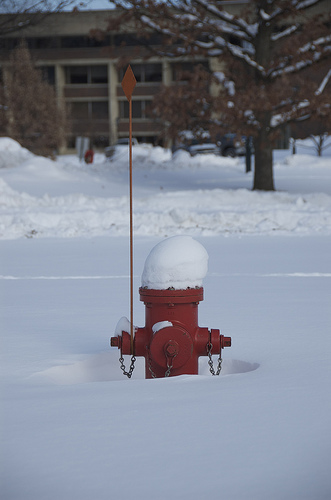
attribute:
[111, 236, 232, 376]
fire hydrant — red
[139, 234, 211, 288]
snow — sunken, white, disheveled, undisturbed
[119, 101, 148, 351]
pole — orange, metal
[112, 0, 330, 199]
tree — large, small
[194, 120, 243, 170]
truck — white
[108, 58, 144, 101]
diamond — orange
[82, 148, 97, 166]
shirt — red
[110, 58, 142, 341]
flag — red, orange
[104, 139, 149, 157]
vehicle — grey